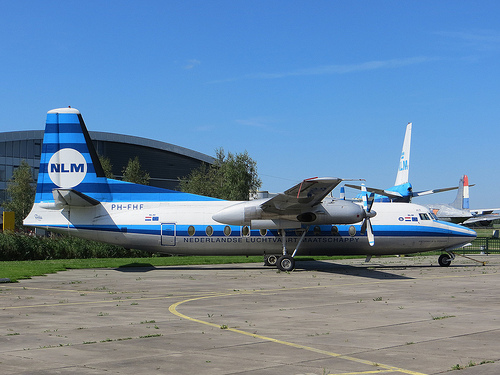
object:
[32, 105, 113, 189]
tail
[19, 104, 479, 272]
aircraft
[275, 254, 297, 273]
tire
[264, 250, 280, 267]
tire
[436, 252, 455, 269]
tire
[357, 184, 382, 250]
propeller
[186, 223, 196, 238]
window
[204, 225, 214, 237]
window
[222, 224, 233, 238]
window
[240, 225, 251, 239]
window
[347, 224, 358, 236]
window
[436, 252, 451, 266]
front wheel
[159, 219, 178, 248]
door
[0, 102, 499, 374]
airport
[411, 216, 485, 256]
nose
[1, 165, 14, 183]
windows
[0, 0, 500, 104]
sky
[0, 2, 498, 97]
clouds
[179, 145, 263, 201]
hedge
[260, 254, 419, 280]
shadow cast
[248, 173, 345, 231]
wing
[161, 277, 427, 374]
lines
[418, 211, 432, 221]
windows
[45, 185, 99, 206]
small wing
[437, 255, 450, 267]
wheel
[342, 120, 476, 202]
airplane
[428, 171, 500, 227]
airplane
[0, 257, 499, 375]
runway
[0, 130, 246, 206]
building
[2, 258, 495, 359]
ground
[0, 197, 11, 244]
post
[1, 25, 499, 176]
background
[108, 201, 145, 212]
letters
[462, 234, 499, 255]
fence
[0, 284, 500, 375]
tarmac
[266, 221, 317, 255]
gear